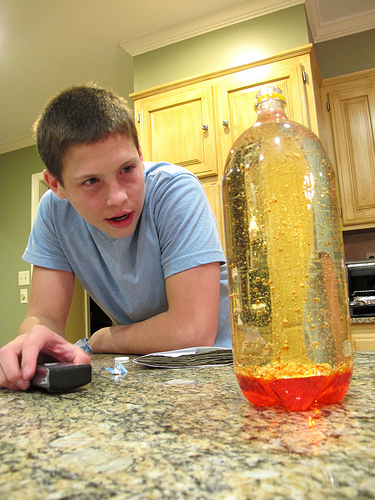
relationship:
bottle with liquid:
[221, 83, 355, 411] [236, 362, 351, 408]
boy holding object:
[0, 84, 232, 395] [28, 361, 93, 395]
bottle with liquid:
[221, 83, 355, 411] [226, 127, 348, 397]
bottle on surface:
[221, 83, 355, 411] [0, 350, 375, 500]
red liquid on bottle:
[235, 367, 356, 410] [221, 83, 355, 411]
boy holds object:
[3, 80, 232, 395] [28, 361, 93, 395]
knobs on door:
[200, 122, 207, 130] [132, 82, 217, 181]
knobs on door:
[219, 118, 230, 129] [213, 61, 307, 171]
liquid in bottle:
[223, 110, 352, 410] [221, 83, 355, 411]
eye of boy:
[121, 164, 135, 174] [0, 84, 232, 395]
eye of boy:
[81, 171, 105, 195] [0, 84, 232, 395]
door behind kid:
[129, 78, 224, 179] [7, 73, 262, 402]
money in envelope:
[138, 338, 248, 380] [124, 336, 243, 382]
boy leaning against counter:
[0, 84, 232, 395] [2, 348, 373, 498]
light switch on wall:
[17, 270, 29, 285] [0, 118, 129, 376]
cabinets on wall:
[173, 77, 255, 115] [2, 17, 362, 325]